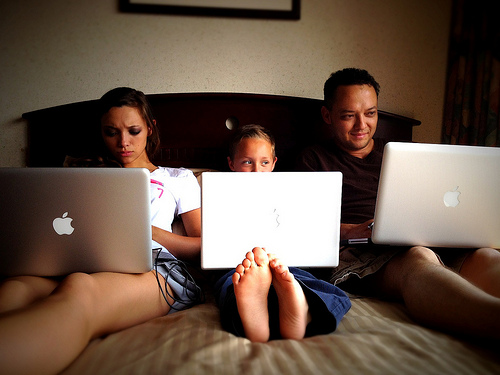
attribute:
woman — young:
[58, 82, 198, 311]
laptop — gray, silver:
[5, 164, 154, 281]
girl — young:
[202, 121, 333, 354]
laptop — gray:
[194, 169, 347, 275]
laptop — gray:
[368, 137, 498, 258]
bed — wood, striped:
[17, 83, 487, 372]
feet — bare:
[222, 245, 311, 348]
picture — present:
[115, 2, 304, 31]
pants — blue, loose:
[209, 265, 353, 337]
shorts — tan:
[333, 247, 393, 283]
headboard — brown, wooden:
[11, 87, 418, 143]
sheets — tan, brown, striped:
[110, 338, 461, 368]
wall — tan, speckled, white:
[13, 8, 448, 95]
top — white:
[146, 159, 200, 243]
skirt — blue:
[158, 249, 197, 315]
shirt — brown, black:
[310, 146, 379, 218]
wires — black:
[151, 243, 202, 314]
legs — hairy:
[390, 247, 496, 346]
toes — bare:
[226, 246, 299, 287]